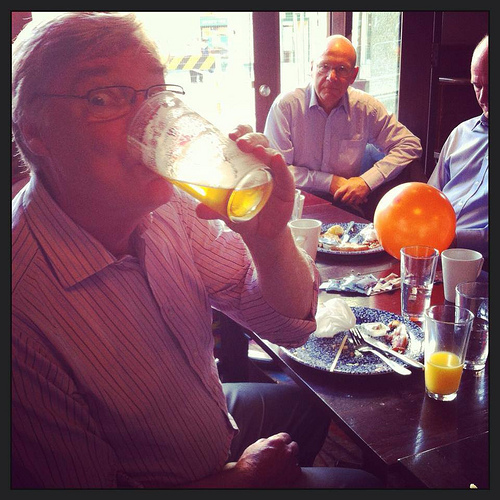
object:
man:
[7, 16, 319, 499]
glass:
[124, 94, 275, 227]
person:
[265, 19, 422, 201]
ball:
[365, 180, 467, 267]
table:
[175, 172, 493, 484]